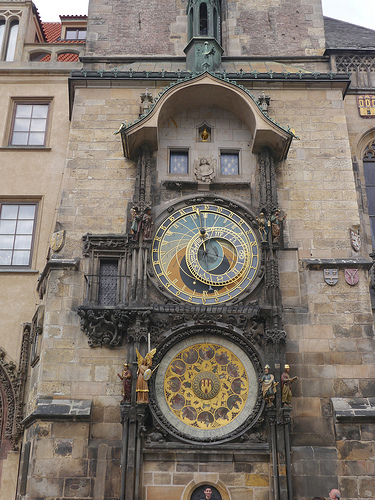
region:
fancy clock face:
[145, 199, 258, 304]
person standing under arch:
[200, 487, 213, 497]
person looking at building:
[327, 487, 340, 499]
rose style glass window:
[153, 330, 259, 436]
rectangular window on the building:
[0, 194, 41, 273]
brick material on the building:
[140, 450, 272, 498]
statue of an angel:
[131, 347, 157, 403]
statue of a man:
[260, 359, 279, 407]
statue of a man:
[280, 360, 296, 407]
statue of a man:
[116, 361, 132, 403]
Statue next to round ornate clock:
[255, 362, 279, 405]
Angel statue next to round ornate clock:
[130, 342, 154, 404]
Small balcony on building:
[80, 270, 134, 304]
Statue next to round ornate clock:
[140, 201, 151, 239]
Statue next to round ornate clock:
[251, 204, 268, 246]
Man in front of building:
[193, 484, 218, 499]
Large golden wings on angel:
[128, 345, 157, 369]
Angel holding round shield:
[135, 342, 157, 404]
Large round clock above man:
[146, 321, 266, 451]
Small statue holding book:
[279, 361, 302, 401]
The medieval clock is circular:
[156, 199, 257, 315]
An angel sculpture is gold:
[139, 352, 156, 410]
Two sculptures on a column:
[260, 364, 298, 414]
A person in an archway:
[196, 479, 226, 499]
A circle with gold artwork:
[170, 343, 248, 427]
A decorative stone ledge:
[89, 304, 167, 345]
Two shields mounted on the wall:
[321, 269, 360, 292]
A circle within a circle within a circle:
[165, 210, 257, 302]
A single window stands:
[4, 196, 38, 274]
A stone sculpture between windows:
[194, 152, 217, 193]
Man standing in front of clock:
[190, 488, 225, 498]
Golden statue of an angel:
[133, 349, 158, 405]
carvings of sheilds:
[317, 263, 361, 293]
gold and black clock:
[154, 208, 257, 303]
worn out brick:
[34, 418, 89, 496]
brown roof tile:
[42, 18, 62, 43]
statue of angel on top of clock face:
[188, 155, 220, 190]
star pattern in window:
[167, 147, 189, 174]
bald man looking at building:
[323, 486, 342, 498]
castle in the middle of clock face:
[190, 368, 220, 400]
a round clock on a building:
[144, 194, 272, 305]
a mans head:
[192, 482, 226, 498]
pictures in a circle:
[146, 333, 266, 462]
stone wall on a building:
[301, 282, 370, 400]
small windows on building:
[161, 139, 260, 187]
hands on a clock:
[191, 200, 209, 260]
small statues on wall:
[257, 359, 299, 412]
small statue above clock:
[184, 154, 220, 185]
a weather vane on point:
[179, 41, 223, 77]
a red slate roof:
[37, 14, 98, 65]